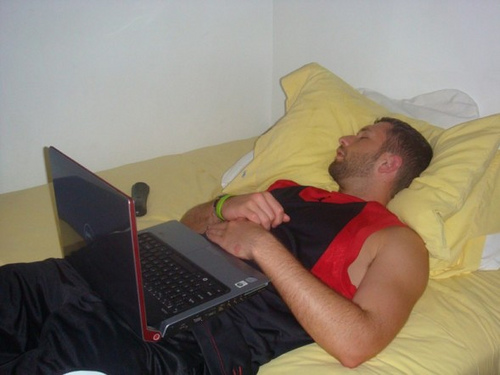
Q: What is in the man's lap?
A: Laptop.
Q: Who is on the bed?
A: A man.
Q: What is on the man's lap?
A: Laptop.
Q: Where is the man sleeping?
A: In a bedroom.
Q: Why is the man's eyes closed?
A: Sleeping.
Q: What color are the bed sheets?
A: Yellow.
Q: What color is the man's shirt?
A: Red and black.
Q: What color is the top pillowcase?
A: Yellow.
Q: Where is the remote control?
A: Beside the man in the bed.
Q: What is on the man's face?
A: A beard.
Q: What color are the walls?
A: White.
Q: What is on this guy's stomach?
A: Laptop.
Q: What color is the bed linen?
A: Yellow.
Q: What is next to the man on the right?
A: Remote.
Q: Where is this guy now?
A: In his room.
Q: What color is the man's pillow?
A: Yellow.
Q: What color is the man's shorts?
A: Black.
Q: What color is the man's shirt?
A: Black and red.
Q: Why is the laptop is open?
A: The guy was using it.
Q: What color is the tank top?
A: Black and red.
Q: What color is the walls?
A: White.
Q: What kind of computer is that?
A: Laptop.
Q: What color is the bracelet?
A: Green.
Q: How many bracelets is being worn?
A: 2.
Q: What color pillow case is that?
A: Yellow.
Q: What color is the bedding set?
A: Yellow.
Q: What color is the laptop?
A: Black, red and gray.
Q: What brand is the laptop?
A: Dell.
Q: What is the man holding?
A: A laptop.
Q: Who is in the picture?
A: A man.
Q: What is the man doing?
A: Sleeping.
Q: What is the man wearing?
A: A tank top.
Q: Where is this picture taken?
A: A bedroom.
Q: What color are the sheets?
A: Yellow.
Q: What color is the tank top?
A: Red and black.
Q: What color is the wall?
A: White.